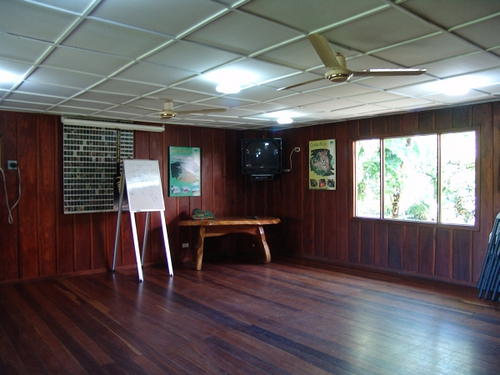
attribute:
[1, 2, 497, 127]
ceiling — white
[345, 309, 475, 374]
reflection — sunlight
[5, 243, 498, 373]
floor — wooden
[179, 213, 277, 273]
table — wooden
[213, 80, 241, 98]
light fixture — ceiling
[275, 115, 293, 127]
light fixture — ceiling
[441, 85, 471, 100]
light fixture — ceiling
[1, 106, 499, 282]
paneling — is wood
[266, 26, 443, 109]
fan — is white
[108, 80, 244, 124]
fan — is white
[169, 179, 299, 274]
table — wooden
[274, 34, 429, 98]
ceiling fan — white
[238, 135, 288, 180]
television — is black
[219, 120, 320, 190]
televison — is mounted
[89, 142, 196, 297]
easel — white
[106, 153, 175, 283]
white board — is white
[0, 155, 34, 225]
wire — connected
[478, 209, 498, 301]
chairs — folding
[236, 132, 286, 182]
television — black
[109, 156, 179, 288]
drawing board — white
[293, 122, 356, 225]
picture — is wood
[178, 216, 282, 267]
table — is wooden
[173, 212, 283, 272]
table — wooden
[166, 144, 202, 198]
frame — is black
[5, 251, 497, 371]
wood floor — dark 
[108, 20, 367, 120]
design — square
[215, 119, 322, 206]
television — mounted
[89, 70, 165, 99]
tile — ceiling tile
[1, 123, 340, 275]
wall — wood